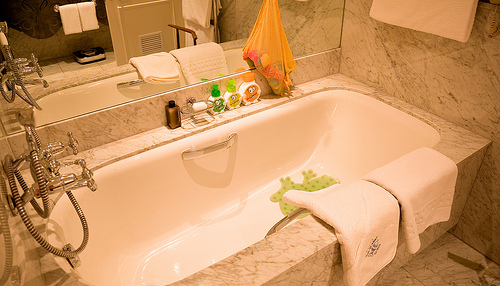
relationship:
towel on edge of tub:
[282, 177, 401, 285] [167, 129, 494, 286]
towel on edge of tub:
[363, 147, 460, 257] [167, 129, 494, 286]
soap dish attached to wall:
[191, 101, 208, 111] [0, 45, 342, 174]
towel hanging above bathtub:
[368, 0, 481, 44] [0, 72, 492, 286]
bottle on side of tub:
[208, 83, 226, 114] [6, 70, 343, 201]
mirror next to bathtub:
[0, 0, 344, 139] [0, 72, 492, 286]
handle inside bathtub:
[183, 130, 237, 166] [0, 72, 492, 286]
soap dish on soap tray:
[191, 101, 208, 111] [178, 97, 213, 118]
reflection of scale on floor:
[69, 44, 106, 65] [381, 232, 499, 285]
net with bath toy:
[240, 0, 297, 96] [257, 50, 270, 68]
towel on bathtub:
[282, 177, 401, 285] [0, 72, 492, 286]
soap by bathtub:
[191, 101, 208, 111] [0, 72, 492, 286]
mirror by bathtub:
[0, 0, 344, 139] [0, 72, 492, 286]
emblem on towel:
[366, 235, 384, 258] [282, 177, 401, 285]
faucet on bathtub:
[0, 34, 100, 263] [0, 72, 492, 286]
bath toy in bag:
[257, 50, 270, 68] [240, 0, 297, 96]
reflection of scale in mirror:
[69, 44, 106, 65] [0, 0, 344, 139]